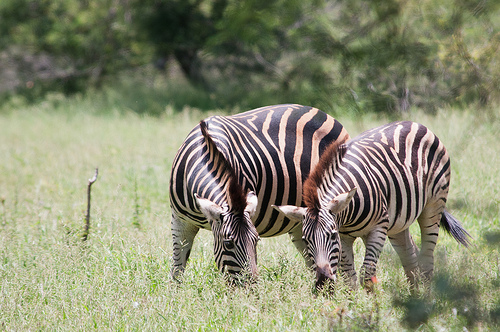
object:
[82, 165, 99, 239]
tall weed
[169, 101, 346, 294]
zebra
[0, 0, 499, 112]
trees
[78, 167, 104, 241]
stick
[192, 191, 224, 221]
ear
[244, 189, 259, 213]
ear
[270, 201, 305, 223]
ear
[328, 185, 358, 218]
ear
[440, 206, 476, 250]
tail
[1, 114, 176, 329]
grass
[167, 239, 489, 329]
grass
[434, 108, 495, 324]
grass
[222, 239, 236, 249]
eye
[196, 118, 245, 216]
black mane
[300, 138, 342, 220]
black mane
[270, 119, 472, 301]
zebra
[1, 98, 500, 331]
ground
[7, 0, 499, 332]
field